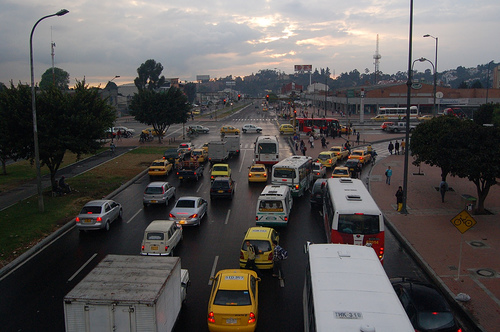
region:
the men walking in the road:
[234, 238, 294, 279]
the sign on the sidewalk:
[446, 205, 481, 285]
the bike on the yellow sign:
[454, 210, 474, 230]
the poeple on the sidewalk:
[381, 160, 452, 212]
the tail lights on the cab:
[205, 309, 256, 327]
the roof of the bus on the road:
[303, 243, 414, 330]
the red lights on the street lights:
[221, 90, 293, 111]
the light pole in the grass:
[25, 5, 67, 222]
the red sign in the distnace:
[292, 60, 312, 73]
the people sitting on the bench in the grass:
[52, 172, 71, 199]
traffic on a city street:
[61, 50, 423, 319]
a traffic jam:
[253, 106, 396, 301]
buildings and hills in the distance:
[151, 43, 499, 105]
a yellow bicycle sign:
[436, 203, 485, 281]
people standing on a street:
[388, 119, 418, 222]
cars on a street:
[38, 101, 431, 318]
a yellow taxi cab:
[203, 262, 291, 330]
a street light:
[20, 11, 79, 211]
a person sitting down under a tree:
[49, 51, 116, 202]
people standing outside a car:
[240, 226, 305, 283]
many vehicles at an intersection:
[58, 115, 463, 329]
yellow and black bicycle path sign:
[448, 207, 478, 282]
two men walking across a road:
[243, 237, 288, 277]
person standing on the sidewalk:
[393, 184, 405, 212]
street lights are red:
[182, 93, 298, 134]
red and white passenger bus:
[318, 175, 386, 262]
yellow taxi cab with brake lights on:
[206, 268, 261, 329]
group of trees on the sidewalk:
[408, 100, 498, 217]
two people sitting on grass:
[49, 174, 74, 195]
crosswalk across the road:
[176, 138, 292, 150]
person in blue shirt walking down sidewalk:
[380, 162, 397, 188]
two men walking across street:
[238, 234, 293, 283]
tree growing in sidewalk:
[407, 107, 498, 221]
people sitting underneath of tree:
[48, 172, 78, 204]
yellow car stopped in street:
[235, 224, 283, 276]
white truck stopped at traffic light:
[201, 137, 234, 169]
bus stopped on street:
[320, 172, 387, 268]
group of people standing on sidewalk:
[384, 135, 407, 156]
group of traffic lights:
[218, 89, 273, 109]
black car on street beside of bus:
[384, 265, 467, 329]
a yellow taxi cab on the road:
[186, 253, 273, 327]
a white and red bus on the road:
[299, 173, 419, 262]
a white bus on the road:
[293, 228, 420, 329]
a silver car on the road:
[159, 188, 206, 224]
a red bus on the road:
[279, 103, 366, 155]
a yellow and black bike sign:
[443, 199, 491, 308]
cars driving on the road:
[121, 106, 379, 141]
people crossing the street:
[273, 115, 380, 164]